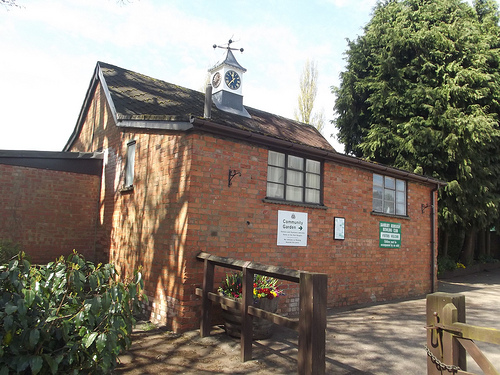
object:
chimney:
[202, 82, 211, 119]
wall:
[183, 131, 438, 330]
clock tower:
[204, 29, 252, 120]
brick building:
[0, 27, 447, 336]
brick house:
[0, 61, 447, 336]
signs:
[276, 209, 308, 246]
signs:
[333, 216, 345, 239]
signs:
[378, 220, 400, 250]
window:
[264, 152, 333, 213]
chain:
[422, 348, 457, 373]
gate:
[425, 288, 499, 374]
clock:
[222, 69, 241, 90]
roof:
[58, 57, 450, 184]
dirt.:
[354, 301, 401, 366]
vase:
[258, 294, 275, 305]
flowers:
[259, 276, 282, 299]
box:
[215, 267, 284, 340]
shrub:
[0, 249, 143, 374]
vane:
[208, 30, 253, 59]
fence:
[193, 249, 499, 373]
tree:
[329, 0, 499, 276]